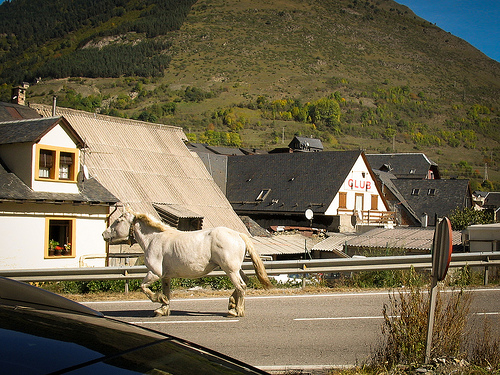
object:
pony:
[102, 200, 273, 320]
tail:
[240, 231, 273, 291]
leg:
[138, 266, 170, 306]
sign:
[429, 217, 451, 281]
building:
[0, 79, 118, 270]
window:
[47, 219, 73, 257]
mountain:
[2, 2, 500, 194]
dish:
[305, 208, 315, 219]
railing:
[0, 251, 500, 284]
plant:
[56, 245, 65, 250]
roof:
[225, 148, 361, 213]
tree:
[315, 99, 342, 128]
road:
[59, 286, 498, 369]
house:
[196, 154, 395, 234]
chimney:
[72, 141, 92, 165]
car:
[1, 275, 273, 375]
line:
[81, 285, 497, 303]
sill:
[47, 255, 75, 259]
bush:
[373, 266, 475, 368]